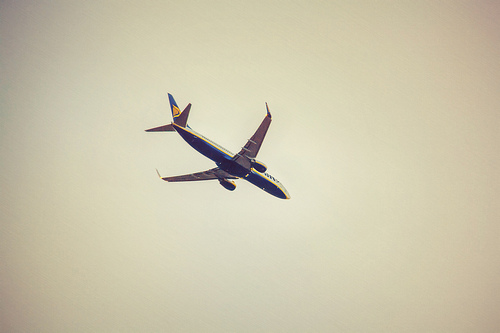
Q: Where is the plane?
A: In the air.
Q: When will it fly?
A: Now.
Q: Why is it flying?
A: To get somewhere.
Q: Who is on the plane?
A: People.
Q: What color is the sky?
A: Gray.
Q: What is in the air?
A: Plane.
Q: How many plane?
A: 1.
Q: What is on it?
A: Strips.